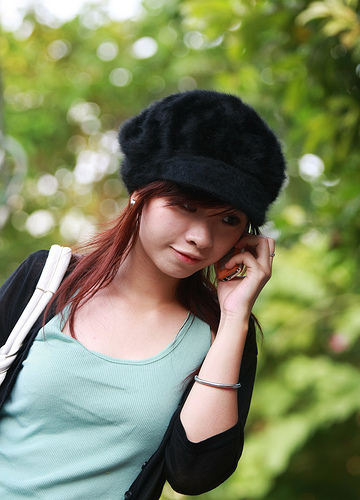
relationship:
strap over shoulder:
[36, 244, 75, 381] [0, 243, 90, 301]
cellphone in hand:
[220, 230, 267, 283] [205, 227, 287, 302]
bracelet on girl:
[189, 374, 247, 393] [0, 86, 295, 497]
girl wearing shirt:
[0, 86, 295, 497] [0, 292, 220, 495]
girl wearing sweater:
[0, 86, 295, 497] [140, 293, 272, 498]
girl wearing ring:
[0, 86, 295, 497] [266, 251, 280, 261]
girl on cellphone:
[0, 86, 295, 497] [220, 230, 267, 283]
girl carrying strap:
[0, 86, 295, 497] [36, 244, 75, 381]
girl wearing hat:
[0, 86, 295, 497] [118, 84, 295, 229]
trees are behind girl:
[15, 17, 344, 94] [0, 86, 295, 497]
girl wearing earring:
[0, 86, 295, 497] [124, 187, 142, 209]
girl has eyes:
[0, 86, 295, 497] [166, 193, 245, 231]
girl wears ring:
[0, 86, 295, 497] [266, 251, 280, 261]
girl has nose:
[0, 86, 295, 497] [181, 213, 225, 256]